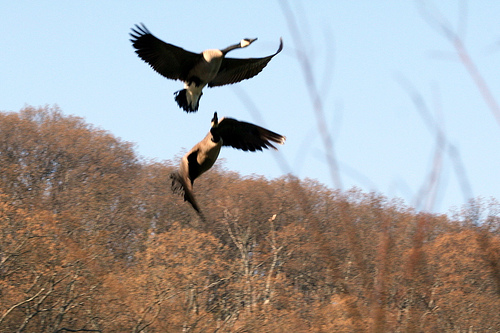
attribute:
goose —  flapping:
[162, 109, 284, 219]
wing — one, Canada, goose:
[100, 21, 212, 92]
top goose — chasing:
[125, 21, 286, 112]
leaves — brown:
[1, 109, 140, 180]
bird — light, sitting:
[266, 212, 280, 224]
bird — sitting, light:
[120, 21, 285, 116]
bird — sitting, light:
[171, 112, 286, 224]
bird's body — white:
[183, 124, 243, 181]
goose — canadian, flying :
[115, 10, 305, 117]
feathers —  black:
[173, 84, 207, 113]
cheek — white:
[236, 39, 250, 49]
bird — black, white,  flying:
[128, 19, 283, 111]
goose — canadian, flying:
[124, 10, 291, 115]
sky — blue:
[5, 3, 464, 39]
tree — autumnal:
[218, 200, 328, 320]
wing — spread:
[116, 14, 186, 89]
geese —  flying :
[129, 27, 286, 110]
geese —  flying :
[171, 107, 279, 224]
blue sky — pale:
[1, 0, 498, 253]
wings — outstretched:
[125, 17, 285, 86]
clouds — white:
[59, 21, 101, 96]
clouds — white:
[71, 28, 105, 88]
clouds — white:
[411, 49, 465, 132]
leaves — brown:
[5, 111, 499, 331]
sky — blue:
[1, 0, 499, 218]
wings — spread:
[111, 22, 289, 89]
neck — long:
[223, 41, 239, 61]